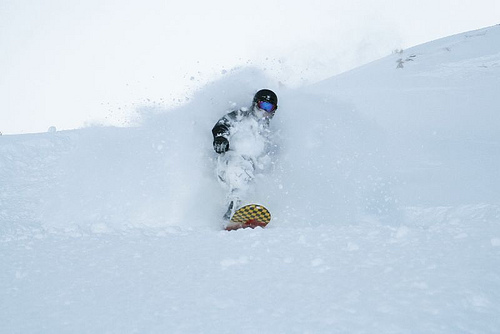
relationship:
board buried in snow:
[229, 203, 271, 227] [0, 23, 497, 332]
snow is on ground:
[0, 23, 497, 332] [0, 24, 497, 333]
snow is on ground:
[321, 96, 497, 332] [27, 97, 488, 326]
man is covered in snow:
[211, 89, 278, 221] [0, 23, 497, 332]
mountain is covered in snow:
[355, 31, 498, 138] [23, 165, 495, 315]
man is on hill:
[211, 89, 278, 221] [1, 0, 498, 332]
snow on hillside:
[359, 250, 411, 279] [80, 121, 210, 281]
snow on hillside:
[71, 240, 114, 267] [80, 121, 210, 281]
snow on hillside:
[11, 242, 52, 269] [80, 121, 210, 281]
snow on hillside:
[144, 240, 174, 267] [80, 121, 210, 281]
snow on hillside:
[450, 215, 480, 240] [80, 121, 210, 281]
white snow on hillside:
[339, 47, 420, 230] [32, 125, 208, 276]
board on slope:
[229, 203, 271, 227] [301, 26, 439, 195]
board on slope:
[229, 203, 271, 227] [294, 62, 493, 310]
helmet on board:
[249, 87, 281, 112] [229, 203, 271, 227]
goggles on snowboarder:
[250, 94, 291, 114] [199, 82, 281, 231]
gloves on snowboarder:
[206, 131, 243, 167] [206, 74, 289, 241]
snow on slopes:
[22, 133, 144, 258] [24, 102, 497, 292]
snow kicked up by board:
[366, 155, 425, 259] [222, 197, 272, 227]